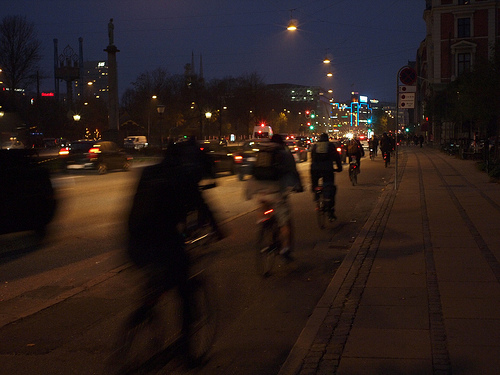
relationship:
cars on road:
[0, 130, 73, 253] [22, 119, 358, 360]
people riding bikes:
[114, 106, 431, 308] [80, 92, 420, 338]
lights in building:
[291, 54, 401, 145] [272, 29, 402, 130]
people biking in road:
[83, 105, 417, 326] [0, 146, 390, 375]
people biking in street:
[100, 85, 421, 305] [16, 96, 423, 363]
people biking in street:
[112, 119, 408, 309] [2, 113, 394, 371]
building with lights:
[335, 90, 379, 130] [356, 104, 361, 125]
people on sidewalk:
[409, 121, 429, 155] [324, 154, 484, 362]